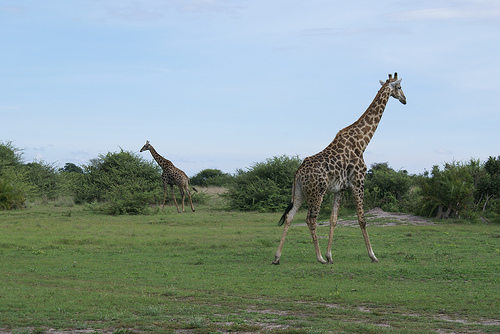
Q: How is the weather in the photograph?
A: It is cloudy.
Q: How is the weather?
A: It is cloudy.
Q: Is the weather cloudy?
A: Yes, it is cloudy.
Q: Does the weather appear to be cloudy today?
A: Yes, it is cloudy.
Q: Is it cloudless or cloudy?
A: It is cloudy.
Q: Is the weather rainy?
A: No, it is cloudy.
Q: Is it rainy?
A: No, it is cloudy.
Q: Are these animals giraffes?
A: Yes, all the animals are giraffes.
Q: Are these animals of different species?
A: No, all the animals are giraffes.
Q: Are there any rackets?
A: No, there are no rackets.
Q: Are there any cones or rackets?
A: No, there are no rackets or cones.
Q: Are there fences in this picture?
A: No, there are no fences.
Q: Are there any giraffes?
A: Yes, there is a giraffe.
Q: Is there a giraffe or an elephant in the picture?
A: Yes, there is a giraffe.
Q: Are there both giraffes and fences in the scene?
A: No, there is a giraffe but no fences.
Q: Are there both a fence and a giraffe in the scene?
A: No, there is a giraffe but no fences.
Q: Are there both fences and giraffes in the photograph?
A: No, there is a giraffe but no fences.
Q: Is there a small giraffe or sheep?
A: Yes, there is a small giraffe.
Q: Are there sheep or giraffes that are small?
A: Yes, the giraffe is small.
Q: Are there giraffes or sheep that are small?
A: Yes, the giraffe is small.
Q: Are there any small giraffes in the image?
A: Yes, there is a small giraffe.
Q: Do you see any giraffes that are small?
A: Yes, there is a giraffe that is small.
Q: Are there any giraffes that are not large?
A: Yes, there is a small giraffe.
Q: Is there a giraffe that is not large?
A: Yes, there is a small giraffe.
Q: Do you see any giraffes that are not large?
A: Yes, there is a small giraffe.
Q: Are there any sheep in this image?
A: No, there are no sheep.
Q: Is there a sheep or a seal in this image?
A: No, there are no sheep or seals.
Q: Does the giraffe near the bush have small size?
A: Yes, the giraffe is small.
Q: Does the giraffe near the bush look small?
A: Yes, the giraffe is small.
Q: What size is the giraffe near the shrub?
A: The giraffe is small.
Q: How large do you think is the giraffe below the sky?
A: The giraffe is small.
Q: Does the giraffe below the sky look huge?
A: No, the giraffe is small.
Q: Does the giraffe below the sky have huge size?
A: No, the giraffe is small.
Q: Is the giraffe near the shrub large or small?
A: The giraffe is small.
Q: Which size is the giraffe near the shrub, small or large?
A: The giraffe is small.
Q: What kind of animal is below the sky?
A: The animal is a giraffe.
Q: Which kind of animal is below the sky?
A: The animal is a giraffe.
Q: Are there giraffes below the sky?
A: Yes, there is a giraffe below the sky.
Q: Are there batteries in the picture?
A: No, there are no batteries.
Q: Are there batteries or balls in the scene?
A: No, there are no batteries or balls.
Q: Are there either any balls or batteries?
A: No, there are no batteries or balls.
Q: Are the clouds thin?
A: Yes, the clouds are thin.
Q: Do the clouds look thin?
A: Yes, the clouds are thin.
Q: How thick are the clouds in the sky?
A: The clouds are thin.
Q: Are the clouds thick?
A: No, the clouds are thin.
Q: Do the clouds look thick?
A: No, the clouds are thin.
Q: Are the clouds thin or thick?
A: The clouds are thin.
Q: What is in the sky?
A: The clouds are in the sky.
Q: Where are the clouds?
A: The clouds are in the sky.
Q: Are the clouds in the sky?
A: Yes, the clouds are in the sky.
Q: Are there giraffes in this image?
A: Yes, there is a giraffe.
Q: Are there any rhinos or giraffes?
A: Yes, there is a giraffe.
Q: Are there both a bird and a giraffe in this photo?
A: No, there is a giraffe but no birds.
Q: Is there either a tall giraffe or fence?
A: Yes, there is a tall giraffe.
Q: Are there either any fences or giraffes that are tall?
A: Yes, the giraffe is tall.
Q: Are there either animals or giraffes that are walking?
A: Yes, the giraffe is walking.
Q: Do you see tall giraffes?
A: Yes, there is a tall giraffe.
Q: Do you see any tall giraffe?
A: Yes, there is a tall giraffe.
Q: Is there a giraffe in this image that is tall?
A: Yes, there is a giraffe that is tall.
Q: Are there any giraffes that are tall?
A: Yes, there is a giraffe that is tall.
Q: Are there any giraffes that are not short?
A: Yes, there is a tall giraffe.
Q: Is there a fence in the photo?
A: No, there are no fences.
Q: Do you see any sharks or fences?
A: No, there are no fences or sharks.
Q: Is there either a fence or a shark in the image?
A: No, there are no fences or sharks.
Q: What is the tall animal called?
A: The animal is a giraffe.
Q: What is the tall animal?
A: The animal is a giraffe.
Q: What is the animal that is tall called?
A: The animal is a giraffe.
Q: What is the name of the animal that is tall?
A: The animal is a giraffe.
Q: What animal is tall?
A: The animal is a giraffe.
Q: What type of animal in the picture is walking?
A: The animal is a giraffe.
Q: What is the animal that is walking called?
A: The animal is a giraffe.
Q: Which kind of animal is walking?
A: The animal is a giraffe.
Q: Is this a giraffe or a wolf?
A: This is a giraffe.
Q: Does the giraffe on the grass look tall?
A: Yes, the giraffe is tall.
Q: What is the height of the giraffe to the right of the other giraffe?
A: The giraffe is tall.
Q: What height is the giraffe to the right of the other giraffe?
A: The giraffe is tall.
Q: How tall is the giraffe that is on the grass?
A: The giraffe is tall.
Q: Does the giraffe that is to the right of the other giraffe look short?
A: No, the giraffe is tall.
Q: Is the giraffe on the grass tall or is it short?
A: The giraffe is tall.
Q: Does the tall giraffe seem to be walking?
A: Yes, the giraffe is walking.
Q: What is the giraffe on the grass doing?
A: The giraffe is walking.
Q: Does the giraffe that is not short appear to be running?
A: No, the giraffe is walking.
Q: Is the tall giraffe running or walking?
A: The giraffe is walking.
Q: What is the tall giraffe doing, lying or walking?
A: The giraffe is walking.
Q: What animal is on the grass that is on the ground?
A: The giraffe is on the grass.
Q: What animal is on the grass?
A: The animal is a giraffe.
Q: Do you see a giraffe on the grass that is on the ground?
A: Yes, there is a giraffe on the grass.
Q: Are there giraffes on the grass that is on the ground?
A: Yes, there is a giraffe on the grass.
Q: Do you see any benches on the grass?
A: No, there is a giraffe on the grass.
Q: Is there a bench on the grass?
A: No, there is a giraffe on the grass.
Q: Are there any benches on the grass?
A: No, there is a giraffe on the grass.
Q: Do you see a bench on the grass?
A: No, there is a giraffe on the grass.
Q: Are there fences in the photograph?
A: No, there are no fences.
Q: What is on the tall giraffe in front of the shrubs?
A: The spots are on the giraffe.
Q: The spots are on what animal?
A: The spots are on the giraffe.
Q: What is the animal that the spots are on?
A: The animal is a giraffe.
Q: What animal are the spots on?
A: The spots are on the giraffe.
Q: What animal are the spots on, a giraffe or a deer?
A: The spots are on a giraffe.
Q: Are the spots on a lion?
A: No, the spots are on a giraffe.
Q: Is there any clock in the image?
A: No, there are no clocks.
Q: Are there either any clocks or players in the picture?
A: No, there are no clocks or players.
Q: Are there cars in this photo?
A: No, there are no cars.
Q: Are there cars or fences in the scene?
A: No, there are no cars or fences.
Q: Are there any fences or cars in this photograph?
A: No, there are no cars or fences.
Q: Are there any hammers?
A: No, there are no hammers.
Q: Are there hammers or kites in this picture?
A: No, there are no hammers or kites.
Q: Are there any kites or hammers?
A: No, there are no hammers or kites.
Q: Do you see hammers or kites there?
A: No, there are no hammers or kites.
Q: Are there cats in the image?
A: No, there are no cats.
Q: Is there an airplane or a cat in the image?
A: No, there are no cats or airplanes.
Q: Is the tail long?
A: Yes, the tail is long.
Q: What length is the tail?
A: The tail is long.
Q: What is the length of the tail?
A: The tail is long.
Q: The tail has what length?
A: The tail is long.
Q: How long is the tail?
A: The tail is long.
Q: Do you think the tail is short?
A: No, the tail is long.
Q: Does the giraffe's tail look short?
A: No, the tail is long.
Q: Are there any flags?
A: No, there are no flags.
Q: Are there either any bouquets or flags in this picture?
A: No, there are no flags or bouquets.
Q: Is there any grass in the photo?
A: Yes, there is grass.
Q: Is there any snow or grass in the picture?
A: Yes, there is grass.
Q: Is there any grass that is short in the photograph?
A: Yes, there is short grass.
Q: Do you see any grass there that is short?
A: Yes, there is grass that is short.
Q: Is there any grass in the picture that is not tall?
A: Yes, there is short grass.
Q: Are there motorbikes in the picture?
A: No, there are no motorbikes.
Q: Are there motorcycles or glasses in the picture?
A: No, there are no motorcycles or glasses.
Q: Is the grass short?
A: Yes, the grass is short.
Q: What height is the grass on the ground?
A: The grass is short.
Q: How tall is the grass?
A: The grass is short.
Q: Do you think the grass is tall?
A: No, the grass is short.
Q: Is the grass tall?
A: No, the grass is short.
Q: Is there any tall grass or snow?
A: No, there is grass but it is short.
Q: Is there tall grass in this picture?
A: No, there is grass but it is short.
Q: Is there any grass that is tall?
A: No, there is grass but it is short.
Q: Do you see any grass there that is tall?
A: No, there is grass but it is short.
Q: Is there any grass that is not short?
A: No, there is grass but it is short.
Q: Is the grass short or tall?
A: The grass is short.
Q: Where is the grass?
A: The grass is on the ground.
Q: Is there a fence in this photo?
A: No, there are no fences.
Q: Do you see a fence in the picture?
A: No, there are no fences.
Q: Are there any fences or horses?
A: No, there are no fences or horses.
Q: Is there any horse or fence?
A: No, there are no fences or horses.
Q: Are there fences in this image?
A: No, there are no fences.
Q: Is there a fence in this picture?
A: No, there are no fences.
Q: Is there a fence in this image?
A: No, there are no fences.